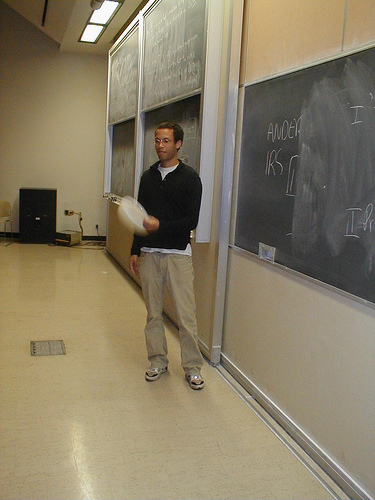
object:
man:
[130, 122, 205, 388]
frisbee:
[104, 191, 151, 239]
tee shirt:
[138, 246, 194, 255]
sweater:
[130, 158, 204, 258]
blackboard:
[233, 43, 373, 303]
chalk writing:
[251, 96, 373, 236]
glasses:
[153, 136, 170, 144]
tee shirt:
[157, 161, 173, 174]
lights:
[82, 0, 119, 44]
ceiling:
[0, 0, 143, 54]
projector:
[53, 207, 82, 247]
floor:
[0, 221, 344, 500]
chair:
[2, 196, 14, 242]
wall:
[1, 53, 100, 242]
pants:
[140, 245, 204, 369]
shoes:
[185, 363, 205, 390]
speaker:
[96, 223, 106, 246]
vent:
[31, 338, 68, 355]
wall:
[209, 0, 374, 482]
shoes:
[144, 360, 169, 382]